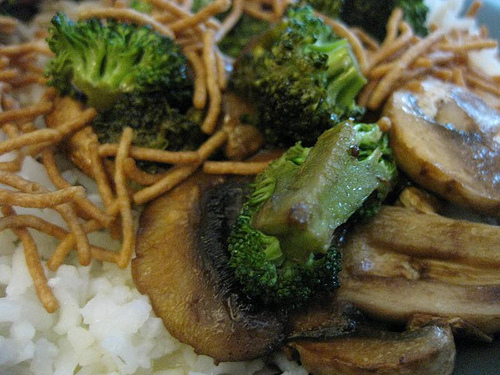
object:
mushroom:
[384, 85, 499, 216]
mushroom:
[277, 309, 467, 375]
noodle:
[1, 203, 62, 317]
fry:
[3, 5, 498, 373]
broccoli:
[41, 10, 198, 149]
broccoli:
[226, 19, 368, 146]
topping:
[10, 101, 154, 290]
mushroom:
[127, 163, 496, 368]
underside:
[71, 50, 135, 110]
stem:
[73, 75, 122, 115]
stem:
[326, 32, 368, 89]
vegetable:
[66, 24, 418, 286]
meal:
[1, 0, 498, 373]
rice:
[7, 276, 138, 368]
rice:
[422, 0, 498, 91]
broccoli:
[215, 124, 388, 297]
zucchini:
[127, 178, 211, 367]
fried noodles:
[18, 61, 191, 271]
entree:
[1, 2, 499, 373]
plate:
[0, 0, 499, 373]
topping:
[0, 1, 499, 313]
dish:
[1, 0, 499, 373]